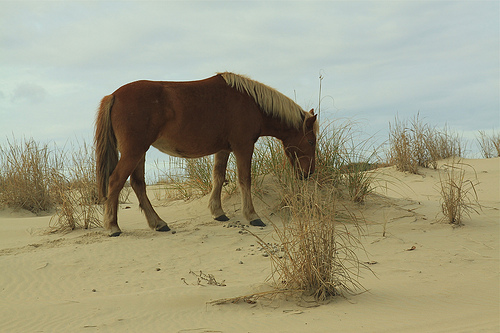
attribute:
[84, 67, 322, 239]
tail — long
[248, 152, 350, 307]
bunch — dry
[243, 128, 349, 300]
grass — tall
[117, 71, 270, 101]
back — brown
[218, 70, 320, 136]
mane — blonde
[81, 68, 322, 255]
horse — brown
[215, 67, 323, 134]
mane — light brown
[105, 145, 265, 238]
legs — brown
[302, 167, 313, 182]
nose — brown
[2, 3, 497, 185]
sky — blue, cloudy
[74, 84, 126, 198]
tail — brown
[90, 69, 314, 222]
horse — brown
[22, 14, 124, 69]
clouds — white